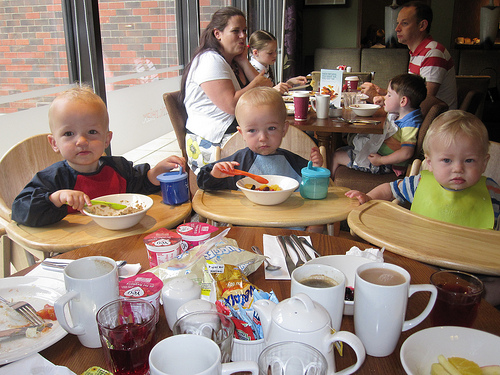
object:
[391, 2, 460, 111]
family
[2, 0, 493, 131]
background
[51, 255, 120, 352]
cups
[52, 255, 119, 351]
cup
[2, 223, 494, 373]
table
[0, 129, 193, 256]
high chair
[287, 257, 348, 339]
cup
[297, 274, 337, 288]
coffee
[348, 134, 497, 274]
high chair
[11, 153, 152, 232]
top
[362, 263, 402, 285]
hot chocolate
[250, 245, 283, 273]
spoon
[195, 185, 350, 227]
part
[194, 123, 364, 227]
high chair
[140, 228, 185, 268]
yogurt cup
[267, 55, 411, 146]
table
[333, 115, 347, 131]
part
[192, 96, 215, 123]
part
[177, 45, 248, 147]
sweater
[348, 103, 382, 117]
bowl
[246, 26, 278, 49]
hair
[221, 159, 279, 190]
spoon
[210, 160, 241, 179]
hand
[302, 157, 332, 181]
lid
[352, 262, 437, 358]
cup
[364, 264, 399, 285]
coffee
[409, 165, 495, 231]
bib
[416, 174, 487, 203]
neck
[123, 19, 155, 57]
bricks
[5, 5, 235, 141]
wall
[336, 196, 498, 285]
table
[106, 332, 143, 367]
liquid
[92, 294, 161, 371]
glass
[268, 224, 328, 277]
silverware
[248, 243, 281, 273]
napkin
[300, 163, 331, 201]
cup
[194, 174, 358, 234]
tray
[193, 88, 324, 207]
baby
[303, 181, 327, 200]
milk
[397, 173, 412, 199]
stripe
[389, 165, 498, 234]
shirt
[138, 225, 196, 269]
cereal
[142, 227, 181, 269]
cup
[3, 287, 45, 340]
fork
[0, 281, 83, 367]
plate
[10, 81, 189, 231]
baby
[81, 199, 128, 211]
spoon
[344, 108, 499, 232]
baby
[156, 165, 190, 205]
cup